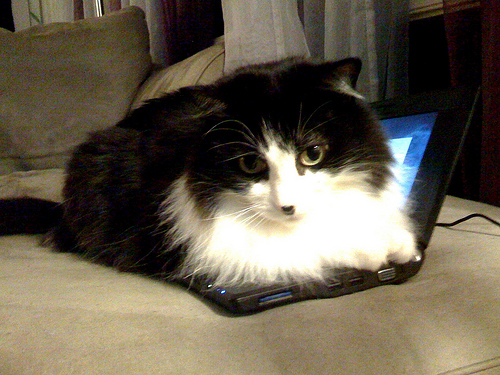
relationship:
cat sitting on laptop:
[0, 55, 419, 287] [178, 85, 481, 316]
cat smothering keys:
[0, 55, 419, 287] [177, 242, 366, 291]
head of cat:
[180, 55, 383, 232] [0, 55, 419, 287]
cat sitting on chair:
[0, 55, 419, 287] [1, 185, 499, 374]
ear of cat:
[318, 56, 363, 102] [0, 55, 419, 287]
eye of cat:
[233, 149, 270, 175] [0, 55, 419, 287]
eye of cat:
[294, 141, 329, 164] [0, 55, 419, 287]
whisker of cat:
[215, 149, 262, 174] [0, 55, 419, 287]